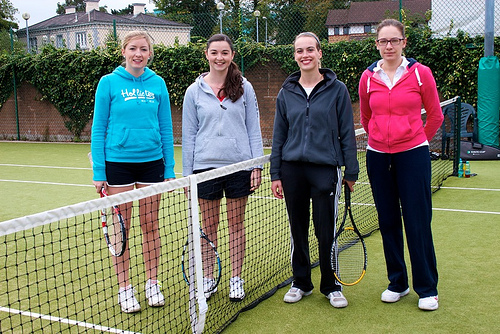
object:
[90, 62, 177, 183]
pull over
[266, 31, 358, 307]
girls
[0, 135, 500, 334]
tennis court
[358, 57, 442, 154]
fleece jacket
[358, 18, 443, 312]
girl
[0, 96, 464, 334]
net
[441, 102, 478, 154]
chair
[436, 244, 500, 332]
grass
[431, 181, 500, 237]
ground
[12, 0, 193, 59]
few homes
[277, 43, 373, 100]
vines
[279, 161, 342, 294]
pants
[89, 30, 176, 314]
girl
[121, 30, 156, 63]
hair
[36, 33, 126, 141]
ivy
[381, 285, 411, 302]
sneaker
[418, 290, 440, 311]
sneaker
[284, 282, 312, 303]
sneaker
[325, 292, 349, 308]
sneaker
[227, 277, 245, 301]
sneaker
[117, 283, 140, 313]
sneaker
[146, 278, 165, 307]
sneaker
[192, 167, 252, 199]
kites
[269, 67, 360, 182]
black jacket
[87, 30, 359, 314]
women smiling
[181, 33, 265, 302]
girl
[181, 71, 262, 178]
grey fleece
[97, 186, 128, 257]
racquet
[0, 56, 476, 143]
brick fence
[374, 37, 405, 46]
glasses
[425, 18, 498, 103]
plants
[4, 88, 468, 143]
wall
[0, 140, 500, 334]
court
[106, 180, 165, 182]
trim